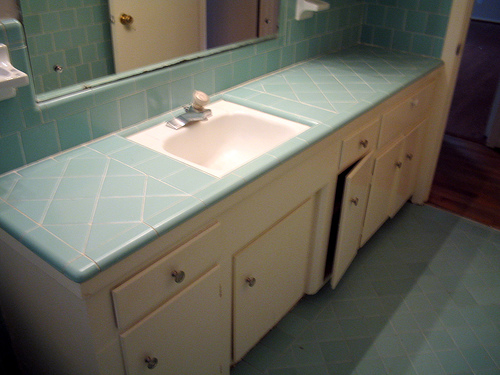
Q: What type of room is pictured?
A: It is a bathroom.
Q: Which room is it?
A: It is a bathroom.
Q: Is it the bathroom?
A: Yes, it is the bathroom.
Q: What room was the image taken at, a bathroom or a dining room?
A: It was taken at a bathroom.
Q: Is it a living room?
A: No, it is a bathroom.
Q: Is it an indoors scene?
A: Yes, it is indoors.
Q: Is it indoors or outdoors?
A: It is indoors.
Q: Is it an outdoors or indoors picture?
A: It is indoors.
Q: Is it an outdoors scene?
A: No, it is indoors.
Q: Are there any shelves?
A: No, there are no shelves.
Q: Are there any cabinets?
A: Yes, there is a cabinet.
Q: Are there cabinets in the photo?
A: Yes, there is a cabinet.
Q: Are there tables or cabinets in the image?
A: Yes, there is a cabinet.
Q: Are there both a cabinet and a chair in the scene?
A: No, there is a cabinet but no chairs.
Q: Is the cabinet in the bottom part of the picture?
A: Yes, the cabinet is in the bottom of the image.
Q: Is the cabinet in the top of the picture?
A: No, the cabinet is in the bottom of the image.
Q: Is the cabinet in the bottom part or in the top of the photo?
A: The cabinet is in the bottom of the image.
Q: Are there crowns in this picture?
A: No, there are no crowns.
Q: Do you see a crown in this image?
A: No, there are no crowns.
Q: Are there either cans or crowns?
A: No, there are no crowns or cans.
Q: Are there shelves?
A: No, there are no shelves.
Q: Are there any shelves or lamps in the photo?
A: No, there are no shelves or lamps.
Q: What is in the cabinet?
A: The drawer is in the cabinet.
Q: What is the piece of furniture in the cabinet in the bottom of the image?
A: The piece of furniture is a drawer.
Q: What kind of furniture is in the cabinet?
A: The piece of furniture is a drawer.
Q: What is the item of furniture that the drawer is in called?
A: The piece of furniture is a cabinet.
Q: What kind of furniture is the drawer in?
A: The drawer is in the cabinet.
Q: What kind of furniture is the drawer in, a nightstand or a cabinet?
A: The drawer is in a cabinet.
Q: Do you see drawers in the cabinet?
A: Yes, there is a drawer in the cabinet.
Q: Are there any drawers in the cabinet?
A: Yes, there is a drawer in the cabinet.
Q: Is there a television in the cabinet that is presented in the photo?
A: No, there is a drawer in the cabinet.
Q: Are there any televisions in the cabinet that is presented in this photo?
A: No, there is a drawer in the cabinet.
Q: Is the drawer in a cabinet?
A: Yes, the drawer is in a cabinet.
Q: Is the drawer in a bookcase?
A: No, the drawer is in a cabinet.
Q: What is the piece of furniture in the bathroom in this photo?
A: The piece of furniture is a drawer.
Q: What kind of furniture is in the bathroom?
A: The piece of furniture is a drawer.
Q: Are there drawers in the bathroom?
A: Yes, there is a drawer in the bathroom.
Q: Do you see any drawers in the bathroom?
A: Yes, there is a drawer in the bathroom.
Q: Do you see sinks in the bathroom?
A: No, there is a drawer in the bathroom.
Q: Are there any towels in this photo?
A: No, there are no towels.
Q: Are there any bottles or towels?
A: No, there are no towels or bottles.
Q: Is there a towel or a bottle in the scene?
A: No, there are no towels or bottles.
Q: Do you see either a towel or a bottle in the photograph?
A: No, there are no towels or bottles.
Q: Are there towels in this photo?
A: No, there are no towels.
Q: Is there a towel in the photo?
A: No, there are no towels.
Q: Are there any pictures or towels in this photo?
A: No, there are no towels or pictures.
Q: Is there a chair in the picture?
A: No, there are no chairs.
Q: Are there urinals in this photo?
A: No, there are no urinals.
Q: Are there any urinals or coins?
A: No, there are no urinals or coins.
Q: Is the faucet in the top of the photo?
A: Yes, the faucet is in the top of the image.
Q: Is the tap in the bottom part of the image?
A: No, the tap is in the top of the image.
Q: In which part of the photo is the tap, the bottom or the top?
A: The tap is in the top of the image.